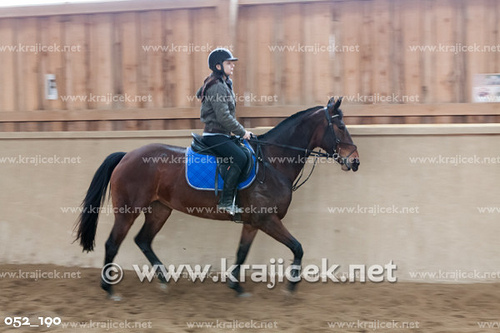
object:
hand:
[242, 130, 254, 138]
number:
[13, 315, 18, 328]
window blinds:
[302, 40, 500, 131]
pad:
[182, 135, 264, 195]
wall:
[439, 171, 492, 280]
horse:
[75, 97, 361, 293]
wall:
[2, 8, 98, 93]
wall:
[179, 236, 234, 265]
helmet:
[206, 47, 236, 66]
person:
[193, 46, 251, 216]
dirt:
[16, 296, 51, 328]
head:
[301, 99, 369, 169]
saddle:
[190, 129, 242, 155]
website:
[130, 258, 403, 285]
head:
[210, 57, 236, 79]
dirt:
[434, 302, 497, 332]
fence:
[0, 6, 495, 118]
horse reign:
[242, 129, 332, 159]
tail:
[72, 149, 125, 253]